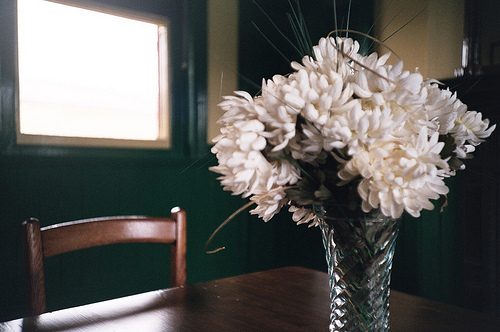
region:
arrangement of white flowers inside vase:
[192, 9, 495, 324]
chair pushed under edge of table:
[19, 190, 465, 327]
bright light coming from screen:
[12, 0, 174, 145]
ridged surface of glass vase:
[317, 212, 395, 326]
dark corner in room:
[205, 7, 459, 284]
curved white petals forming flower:
[357, 120, 445, 215]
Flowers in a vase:
[203, 30, 491, 323]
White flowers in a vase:
[203, 21, 493, 295]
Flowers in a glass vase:
[221, 28, 491, 327]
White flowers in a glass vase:
[196, 15, 495, 316]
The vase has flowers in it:
[283, 169, 442, 326]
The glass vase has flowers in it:
[274, 167, 446, 324]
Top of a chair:
[9, 191, 196, 300]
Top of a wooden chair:
[16, 203, 191, 298]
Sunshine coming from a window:
[15, 3, 172, 152]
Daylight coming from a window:
[9, 1, 175, 153]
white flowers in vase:
[236, 46, 461, 236]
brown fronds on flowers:
[201, 21, 418, 229]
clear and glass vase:
[337, 219, 395, 319]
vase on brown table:
[310, 224, 404, 325]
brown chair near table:
[6, 196, 182, 313]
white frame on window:
[8, 2, 168, 154]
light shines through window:
[22, 19, 197, 171]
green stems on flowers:
[269, 162, 364, 219]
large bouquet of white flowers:
[251, 55, 468, 259]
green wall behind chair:
[40, 157, 225, 209]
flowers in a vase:
[375, 183, 430, 218]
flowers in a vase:
[408, 148, 438, 188]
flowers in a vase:
[456, 97, 488, 147]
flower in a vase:
[370, 113, 411, 150]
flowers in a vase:
[306, 118, 353, 151]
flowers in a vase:
[325, 62, 362, 108]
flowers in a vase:
[270, 68, 301, 105]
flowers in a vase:
[232, 100, 262, 143]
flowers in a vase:
[231, 166, 276, 201]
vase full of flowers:
[213, 13, 467, 330]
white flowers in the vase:
[200, 19, 480, 225]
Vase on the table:
[198, 22, 457, 330]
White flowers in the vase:
[208, 16, 478, 227]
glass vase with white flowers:
[209, 10, 494, 266]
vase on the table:
[300, 198, 416, 330]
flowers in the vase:
[208, 30, 480, 238]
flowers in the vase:
[201, 15, 497, 221]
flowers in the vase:
[193, 29, 477, 245]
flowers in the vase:
[191, 25, 498, 306]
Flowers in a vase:
[221, 35, 441, 228]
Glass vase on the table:
[299, 171, 426, 321]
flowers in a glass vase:
[197, 8, 489, 241]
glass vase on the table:
[203, 55, 450, 330]